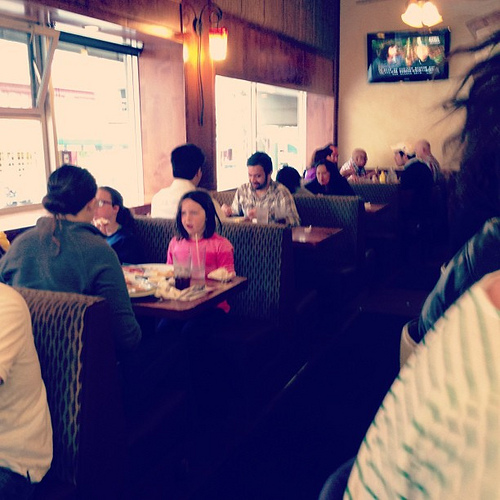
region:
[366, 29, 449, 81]
a small television displaying the news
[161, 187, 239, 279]
a young girl in pink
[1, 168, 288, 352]
a family eating at a booth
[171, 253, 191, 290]
a glass of coca cola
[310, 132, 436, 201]
a family eating out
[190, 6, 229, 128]
a bright lamp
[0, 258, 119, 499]
a restauraunt booth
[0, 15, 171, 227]
an open glass window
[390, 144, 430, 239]
a man in a white cap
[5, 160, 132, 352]
a woman with a ponytail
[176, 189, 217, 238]
Head of child diner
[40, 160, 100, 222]
Head of adult diner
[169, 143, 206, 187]
Head of adult diner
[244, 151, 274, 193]
Head of adult diner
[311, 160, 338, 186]
Head of adult diner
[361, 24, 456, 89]
Framed picture on wall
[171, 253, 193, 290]
Tall beverage clear glass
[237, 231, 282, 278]
Part of padded booth seat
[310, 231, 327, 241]
Part of brown table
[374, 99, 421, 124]
Part of yellow wall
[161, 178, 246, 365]
a child in a pink shirt sitting in a booth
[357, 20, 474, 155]
a tv plays on the wall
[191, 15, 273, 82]
a light above the table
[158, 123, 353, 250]
2 men enjoy a meal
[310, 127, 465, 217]
4 people sit at a table in the back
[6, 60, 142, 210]
the window lets in alot of light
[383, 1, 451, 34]
more light fixtures hang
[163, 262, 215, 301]
a glass of dark liquid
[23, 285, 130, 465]
a white on black booth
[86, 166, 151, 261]
this person is wearing glasses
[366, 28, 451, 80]
tv on wall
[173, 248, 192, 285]
cup on the table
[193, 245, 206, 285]
cup on the table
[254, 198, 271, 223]
cup on the table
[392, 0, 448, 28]
light fixture on the ceiling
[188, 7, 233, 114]
light fixture on the wall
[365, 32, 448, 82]
black flat screen on wall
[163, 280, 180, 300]
napkin on the table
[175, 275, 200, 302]
silverware on the table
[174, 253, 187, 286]
soda in a glass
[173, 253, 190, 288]
plastic clear glass with dark brown soda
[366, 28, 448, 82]
flat screen black TV on the wall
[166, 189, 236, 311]
little girl in a pink shirt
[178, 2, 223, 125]
metal ornament on the wall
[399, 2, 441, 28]
two light fixtures above the TV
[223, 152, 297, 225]
guy in the booth with a beard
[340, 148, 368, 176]
bald man in the black booth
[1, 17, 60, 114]
window section that is open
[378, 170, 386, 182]
yellow bottle on back table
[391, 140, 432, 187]
man in white baseball cap